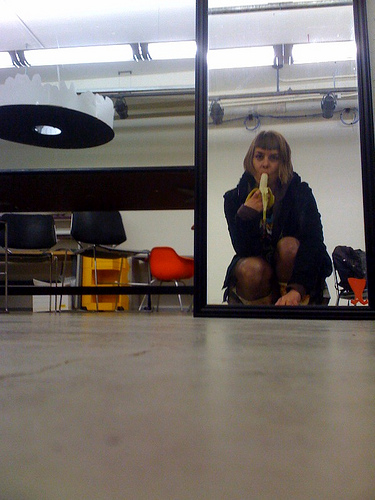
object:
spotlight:
[319, 91, 337, 119]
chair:
[138, 247, 194, 313]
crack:
[0, 348, 153, 381]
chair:
[0, 212, 58, 316]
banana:
[245, 173, 275, 226]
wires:
[208, 105, 361, 132]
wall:
[206, 4, 368, 305]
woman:
[221, 129, 334, 306]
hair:
[243, 130, 294, 184]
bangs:
[255, 136, 280, 151]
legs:
[138, 280, 193, 313]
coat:
[221, 169, 332, 290]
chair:
[58, 208, 152, 315]